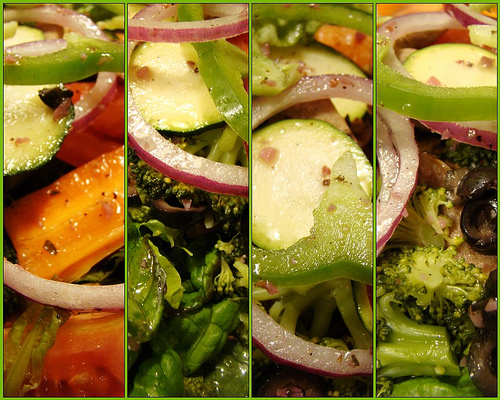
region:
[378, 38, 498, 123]
A green bell pepper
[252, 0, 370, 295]
some green bell peppers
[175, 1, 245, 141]
A green bell pepper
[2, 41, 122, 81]
A green bell pepper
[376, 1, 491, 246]
some seasoned red onions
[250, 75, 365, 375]
some seasoned red onions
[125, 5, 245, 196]
some seasoned red onions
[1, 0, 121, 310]
some seasoned red onions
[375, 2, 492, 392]
A pile of vegetables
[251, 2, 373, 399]
A pile of vegetables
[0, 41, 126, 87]
A slice of green bell pepper.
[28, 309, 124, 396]
Part of a tomato.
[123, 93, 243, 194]
A slice of purple onion.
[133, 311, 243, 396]
Part of a green lettuce leaf.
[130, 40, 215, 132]
A slice of cucumber.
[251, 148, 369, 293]
Another piece of green bell pepper.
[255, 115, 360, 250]
Another slice of cucumber.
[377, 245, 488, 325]
A small piece of broccoli.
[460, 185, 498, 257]
A slice of black olive.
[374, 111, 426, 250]
Two slices of purple onions.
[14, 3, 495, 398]
a vegetable salad with a dressing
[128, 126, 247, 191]
red onions are in the salad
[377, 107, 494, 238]
the red onions are sliced thinly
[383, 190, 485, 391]
broccoli pieces are in the dish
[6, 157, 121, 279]
carrots are slivered in the salad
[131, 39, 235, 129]
sliced cucumbers are throughout the salad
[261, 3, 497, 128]
sliced green peppers are next to the cucumbers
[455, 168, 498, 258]
black olives are in the dish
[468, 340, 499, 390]
green olives are mixed in the dish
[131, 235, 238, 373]
torn kale is in the salad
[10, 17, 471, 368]
colorful vegetable salad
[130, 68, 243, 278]
salad with red onions, cucumber, and broccoli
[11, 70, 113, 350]
salad with bell pepper, red onions, and cucumber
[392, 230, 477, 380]
chopped broccoli florets in salad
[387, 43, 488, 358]
pile of vegetables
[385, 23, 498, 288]
red onions, cucumber, broccoli, black olives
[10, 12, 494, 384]
four-panel closeup of vegetables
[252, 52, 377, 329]
round slices of cucumber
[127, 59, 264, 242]
thinly sliced red onion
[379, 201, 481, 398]
chopped broccoli florets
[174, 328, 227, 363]
crispy piece of green basil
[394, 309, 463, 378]
small stalk of broccoli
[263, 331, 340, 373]
small cut of red onion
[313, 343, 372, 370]
oil on red onion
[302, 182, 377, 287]
piece of green pepper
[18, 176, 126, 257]
thick cut of orange carrot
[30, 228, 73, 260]
pepper flake on orange carrot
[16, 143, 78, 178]
edge of slice of cucumber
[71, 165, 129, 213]
salt flake on carrot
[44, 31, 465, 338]
area filled with fresh vegetables